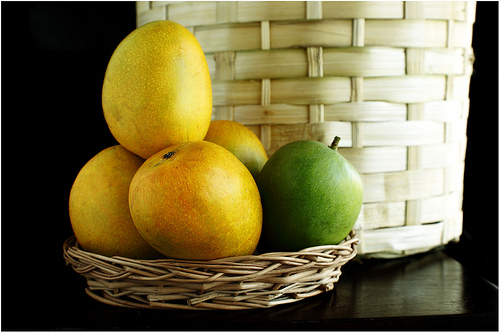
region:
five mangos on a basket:
[50, 7, 373, 318]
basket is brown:
[41, 230, 357, 315]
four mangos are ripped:
[56, 10, 271, 270]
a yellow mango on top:
[95, 10, 221, 171]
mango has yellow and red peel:
[121, 137, 271, 263]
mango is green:
[256, 125, 371, 250]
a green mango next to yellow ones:
[200, 102, 375, 255]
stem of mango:
[322, 126, 349, 162]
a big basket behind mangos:
[132, 2, 488, 266]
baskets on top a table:
[8, 5, 499, 330]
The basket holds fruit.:
[40, 17, 405, 331]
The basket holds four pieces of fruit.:
[36, 12, 407, 323]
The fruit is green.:
[243, 117, 389, 271]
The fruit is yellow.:
[55, 16, 294, 278]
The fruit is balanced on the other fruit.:
[62, 13, 293, 173]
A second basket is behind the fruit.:
[110, 0, 489, 270]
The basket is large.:
[97, 2, 492, 273]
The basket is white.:
[125, 2, 490, 276]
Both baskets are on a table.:
[0, 194, 495, 331]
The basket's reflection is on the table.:
[316, 235, 478, 328]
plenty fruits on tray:
[101, 135, 371, 296]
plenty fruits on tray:
[158, 188, 385, 316]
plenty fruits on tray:
[8, 81, 412, 275]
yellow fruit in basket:
[76, 29, 261, 229]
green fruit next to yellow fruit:
[275, 128, 364, 210]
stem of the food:
[321, 123, 350, 155]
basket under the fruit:
[201, 248, 280, 310]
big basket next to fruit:
[377, 110, 429, 197]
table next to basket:
[383, 255, 435, 315]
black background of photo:
[458, 164, 491, 195]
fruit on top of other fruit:
[88, 9, 220, 131]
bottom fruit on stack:
[129, 147, 239, 273]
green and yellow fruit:
[104, 40, 356, 251]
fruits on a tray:
[127, 117, 367, 289]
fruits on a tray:
[1, 72, 372, 310]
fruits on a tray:
[2, 148, 342, 272]